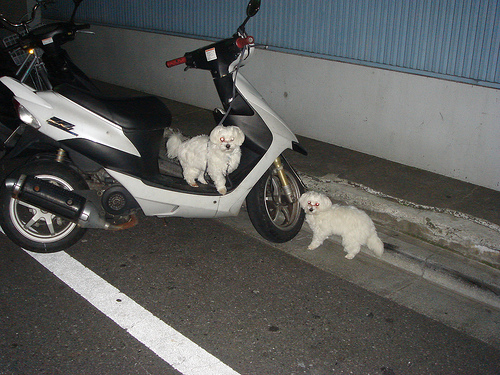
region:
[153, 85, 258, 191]
dog on the bike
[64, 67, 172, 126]
the seat is black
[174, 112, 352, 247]
the dogs are white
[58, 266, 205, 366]
a line on the ground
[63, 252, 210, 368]
the line is white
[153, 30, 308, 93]
the handles are red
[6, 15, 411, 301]
the bike is parked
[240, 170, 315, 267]
the tire is black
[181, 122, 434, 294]
two dogs looking at the camera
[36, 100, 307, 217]
the bike is white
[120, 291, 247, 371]
A white line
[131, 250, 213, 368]
A white line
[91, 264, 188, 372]
A white line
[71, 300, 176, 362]
A white line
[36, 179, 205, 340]
A white line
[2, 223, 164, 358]
A white line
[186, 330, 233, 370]
A white line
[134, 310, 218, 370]
A white line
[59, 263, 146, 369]
A white line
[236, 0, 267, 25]
a small mirror of bike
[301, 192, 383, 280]
a small cute puppy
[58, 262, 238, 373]
a white line on the road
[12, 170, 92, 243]
back tyre of the bike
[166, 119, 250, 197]
a cute white puppy on bike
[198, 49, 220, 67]
a small lable on the bike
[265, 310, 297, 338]
a small dark part on road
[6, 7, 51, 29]
a small handle of a cycle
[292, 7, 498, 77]
an small iron door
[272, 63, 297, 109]
a small dark portion on wall